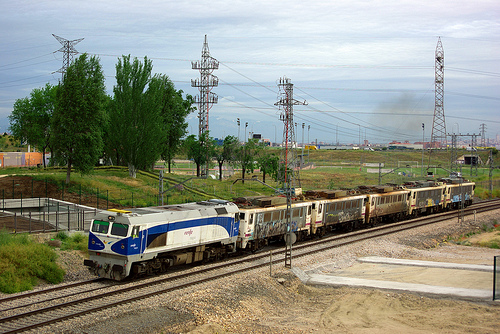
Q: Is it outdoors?
A: Yes, it is outdoors.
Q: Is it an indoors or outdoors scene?
A: It is outdoors.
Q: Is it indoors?
A: No, it is outdoors.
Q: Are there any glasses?
A: No, there are no glasses.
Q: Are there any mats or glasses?
A: No, there are no glasses or mats.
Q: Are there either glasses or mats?
A: No, there are no glasses or mats.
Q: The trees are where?
A: The trees are on the hill.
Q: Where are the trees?
A: The trees are on the hill.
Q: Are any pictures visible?
A: No, there are no pictures.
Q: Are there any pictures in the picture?
A: No, there are no pictures.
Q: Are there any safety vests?
A: No, there are no safety vests.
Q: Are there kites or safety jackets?
A: No, there are no safety jackets or kites.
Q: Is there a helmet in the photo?
A: No, there are no helmets.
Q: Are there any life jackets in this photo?
A: No, there are no life jackets.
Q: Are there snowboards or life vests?
A: No, there are no life vests or snowboards.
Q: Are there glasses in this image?
A: No, there are no glasses.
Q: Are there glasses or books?
A: No, there are no glasses or books.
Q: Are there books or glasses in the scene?
A: No, there are no glasses or books.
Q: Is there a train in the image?
A: Yes, there is a train.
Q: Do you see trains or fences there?
A: Yes, there is a train.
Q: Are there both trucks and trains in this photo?
A: No, there is a train but no trucks.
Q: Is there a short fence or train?
A: Yes, there is a short train.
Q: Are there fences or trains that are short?
A: Yes, the train is short.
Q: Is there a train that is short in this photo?
A: Yes, there is a short train.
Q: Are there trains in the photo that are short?
A: Yes, there is a train that is short.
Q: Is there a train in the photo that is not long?
A: Yes, there is a short train.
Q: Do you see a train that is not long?
A: Yes, there is a short train.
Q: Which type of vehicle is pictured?
A: The vehicle is a train.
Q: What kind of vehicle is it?
A: The vehicle is a train.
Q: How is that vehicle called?
A: This is a train.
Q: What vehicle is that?
A: This is a train.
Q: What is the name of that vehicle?
A: This is a train.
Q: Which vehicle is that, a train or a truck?
A: This is a train.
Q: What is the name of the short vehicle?
A: The vehicle is a train.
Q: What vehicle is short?
A: The vehicle is a train.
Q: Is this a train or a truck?
A: This is a train.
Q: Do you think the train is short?
A: Yes, the train is short.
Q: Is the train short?
A: Yes, the train is short.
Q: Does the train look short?
A: Yes, the train is short.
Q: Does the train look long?
A: No, the train is short.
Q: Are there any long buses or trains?
A: No, there is a train but it is short.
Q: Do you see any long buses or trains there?
A: No, there is a train but it is short.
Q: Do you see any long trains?
A: No, there is a train but it is short.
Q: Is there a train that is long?
A: No, there is a train but it is short.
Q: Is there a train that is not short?
A: No, there is a train but it is short.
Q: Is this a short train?
A: Yes, this is a short train.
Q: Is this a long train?
A: No, this is a short train.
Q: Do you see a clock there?
A: No, there are no clocks.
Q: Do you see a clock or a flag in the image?
A: No, there are no clocks or flags.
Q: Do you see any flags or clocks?
A: No, there are no clocks or flags.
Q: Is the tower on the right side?
A: Yes, the tower is on the right of the image.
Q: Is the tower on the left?
A: No, the tower is on the right of the image.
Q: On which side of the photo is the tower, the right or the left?
A: The tower is on the right of the image.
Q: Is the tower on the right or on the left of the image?
A: The tower is on the right of the image.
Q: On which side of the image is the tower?
A: The tower is on the right of the image.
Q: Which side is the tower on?
A: The tower is on the right of the image.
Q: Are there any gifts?
A: No, there are no gifts.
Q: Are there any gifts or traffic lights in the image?
A: No, there are no gifts or traffic lights.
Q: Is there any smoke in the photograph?
A: Yes, there is smoke.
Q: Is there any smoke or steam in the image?
A: Yes, there is smoke.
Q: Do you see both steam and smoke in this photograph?
A: No, there is smoke but no steam.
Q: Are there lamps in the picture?
A: No, there are no lamps.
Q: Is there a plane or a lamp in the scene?
A: No, there are no lamps or airplanes.